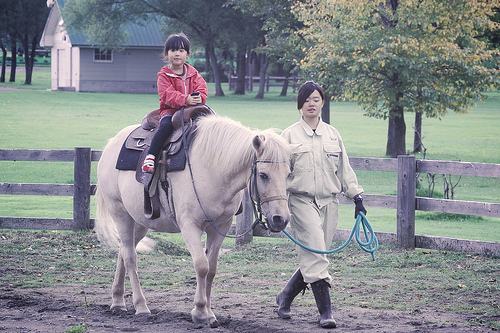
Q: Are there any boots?
A: Yes, there are boots.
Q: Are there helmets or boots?
A: Yes, there are boots.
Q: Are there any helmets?
A: No, there are no helmets.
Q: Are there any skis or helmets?
A: No, there are no helmets or skis.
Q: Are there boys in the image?
A: No, there are no boys.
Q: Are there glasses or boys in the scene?
A: No, there are no boys or glasses.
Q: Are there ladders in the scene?
A: No, there are no ladders.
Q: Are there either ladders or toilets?
A: No, there are no ladders or toilets.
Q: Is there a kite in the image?
A: No, there are no kites.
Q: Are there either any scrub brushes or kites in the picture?
A: No, there are no kites or scrub brushes.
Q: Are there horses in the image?
A: Yes, there is a horse.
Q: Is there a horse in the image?
A: Yes, there is a horse.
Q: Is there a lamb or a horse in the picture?
A: Yes, there is a horse.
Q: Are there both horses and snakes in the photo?
A: No, there is a horse but no snakes.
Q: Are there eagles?
A: No, there are no eagles.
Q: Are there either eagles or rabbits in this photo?
A: No, there are no eagles or rabbits.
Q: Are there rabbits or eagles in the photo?
A: No, there are no eagles or rabbits.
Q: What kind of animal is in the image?
A: The animal is a horse.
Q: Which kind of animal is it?
A: The animal is a horse.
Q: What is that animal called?
A: This is a horse.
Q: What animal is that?
A: This is a horse.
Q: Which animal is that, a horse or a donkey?
A: This is a horse.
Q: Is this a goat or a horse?
A: This is a horse.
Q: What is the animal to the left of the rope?
A: The animal is a horse.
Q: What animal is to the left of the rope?
A: The animal is a horse.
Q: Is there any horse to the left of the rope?
A: Yes, there is a horse to the left of the rope.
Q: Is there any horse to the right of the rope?
A: No, the horse is to the left of the rope.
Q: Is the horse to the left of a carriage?
A: No, the horse is to the left of a rope.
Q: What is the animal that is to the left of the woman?
A: The animal is a horse.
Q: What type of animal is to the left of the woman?
A: The animal is a horse.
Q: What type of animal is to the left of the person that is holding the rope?
A: The animal is a horse.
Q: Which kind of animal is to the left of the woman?
A: The animal is a horse.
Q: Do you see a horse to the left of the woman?
A: Yes, there is a horse to the left of the woman.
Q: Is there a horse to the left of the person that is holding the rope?
A: Yes, there is a horse to the left of the woman.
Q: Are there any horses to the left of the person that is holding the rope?
A: Yes, there is a horse to the left of the woman.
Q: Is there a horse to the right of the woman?
A: No, the horse is to the left of the woman.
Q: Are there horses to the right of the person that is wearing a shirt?
A: No, the horse is to the left of the woman.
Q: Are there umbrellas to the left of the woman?
A: No, there is a horse to the left of the woman.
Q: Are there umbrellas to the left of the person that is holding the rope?
A: No, there is a horse to the left of the woman.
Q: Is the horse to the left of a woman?
A: Yes, the horse is to the left of a woman.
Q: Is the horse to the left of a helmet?
A: No, the horse is to the left of a woman.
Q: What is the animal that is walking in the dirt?
A: The animal is a horse.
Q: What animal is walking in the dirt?
A: The animal is a horse.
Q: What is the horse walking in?
A: The horse is walking in the dirt.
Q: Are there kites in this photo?
A: No, there are no kites.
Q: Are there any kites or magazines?
A: No, there are no kites or magazines.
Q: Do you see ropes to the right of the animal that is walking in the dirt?
A: Yes, there is a rope to the right of the horse.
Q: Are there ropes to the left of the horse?
A: No, the rope is to the right of the horse.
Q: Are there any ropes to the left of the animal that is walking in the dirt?
A: No, the rope is to the right of the horse.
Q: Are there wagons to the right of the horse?
A: No, there is a rope to the right of the horse.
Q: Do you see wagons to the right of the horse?
A: No, there is a rope to the right of the horse.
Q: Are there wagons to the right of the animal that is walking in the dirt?
A: No, there is a rope to the right of the horse.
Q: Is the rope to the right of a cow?
A: No, the rope is to the right of the horse.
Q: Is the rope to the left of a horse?
A: No, the rope is to the right of a horse.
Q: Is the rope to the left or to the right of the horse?
A: The rope is to the right of the horse.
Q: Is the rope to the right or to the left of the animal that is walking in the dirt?
A: The rope is to the right of the horse.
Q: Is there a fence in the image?
A: Yes, there is a fence.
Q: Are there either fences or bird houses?
A: Yes, there is a fence.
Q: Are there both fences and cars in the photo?
A: No, there is a fence but no cars.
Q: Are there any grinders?
A: No, there are no grinders.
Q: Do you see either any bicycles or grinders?
A: No, there are no grinders or bicycles.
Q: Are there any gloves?
A: Yes, there are gloves.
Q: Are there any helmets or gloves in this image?
A: Yes, there are gloves.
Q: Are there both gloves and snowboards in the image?
A: No, there are gloves but no snowboards.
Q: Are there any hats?
A: No, there are no hats.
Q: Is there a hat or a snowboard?
A: No, there are no hats or snowboards.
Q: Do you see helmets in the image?
A: No, there are no helmets.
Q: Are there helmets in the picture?
A: No, there are no helmets.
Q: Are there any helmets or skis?
A: No, there are no helmets or skis.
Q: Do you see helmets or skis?
A: No, there are no helmets or skis.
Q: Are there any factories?
A: No, there are no factories.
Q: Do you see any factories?
A: No, there are no factories.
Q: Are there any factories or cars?
A: No, there are no factories or cars.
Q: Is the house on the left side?
A: Yes, the house is on the left of the image.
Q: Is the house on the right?
A: No, the house is on the left of the image.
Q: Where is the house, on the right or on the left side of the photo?
A: The house is on the left of the image.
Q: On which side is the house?
A: The house is on the left of the image.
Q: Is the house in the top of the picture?
A: Yes, the house is in the top of the image.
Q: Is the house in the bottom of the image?
A: No, the house is in the top of the image.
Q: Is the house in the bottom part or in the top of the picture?
A: The house is in the top of the image.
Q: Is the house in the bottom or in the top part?
A: The house is in the top of the image.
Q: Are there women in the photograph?
A: Yes, there is a woman.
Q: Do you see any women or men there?
A: Yes, there is a woman.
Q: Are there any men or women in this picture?
A: Yes, there is a woman.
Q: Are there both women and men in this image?
A: No, there is a woman but no men.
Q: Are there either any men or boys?
A: No, there are no boys or men.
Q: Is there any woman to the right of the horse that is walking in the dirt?
A: Yes, there is a woman to the right of the horse.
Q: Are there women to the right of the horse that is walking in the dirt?
A: Yes, there is a woman to the right of the horse.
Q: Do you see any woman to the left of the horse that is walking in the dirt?
A: No, the woman is to the right of the horse.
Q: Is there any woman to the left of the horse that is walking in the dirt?
A: No, the woman is to the right of the horse.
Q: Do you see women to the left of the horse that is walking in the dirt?
A: No, the woman is to the right of the horse.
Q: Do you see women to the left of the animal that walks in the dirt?
A: No, the woman is to the right of the horse.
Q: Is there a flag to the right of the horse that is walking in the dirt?
A: No, there is a woman to the right of the horse.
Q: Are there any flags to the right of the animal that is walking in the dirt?
A: No, there is a woman to the right of the horse.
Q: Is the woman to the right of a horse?
A: Yes, the woman is to the right of a horse.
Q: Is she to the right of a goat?
A: No, the woman is to the right of a horse.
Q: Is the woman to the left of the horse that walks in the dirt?
A: No, the woman is to the right of the horse.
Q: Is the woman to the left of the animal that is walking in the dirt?
A: No, the woman is to the right of the horse.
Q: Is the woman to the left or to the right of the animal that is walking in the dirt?
A: The woman is to the right of the horse.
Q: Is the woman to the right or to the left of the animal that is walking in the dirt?
A: The woman is to the right of the horse.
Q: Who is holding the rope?
A: The woman is holding the rope.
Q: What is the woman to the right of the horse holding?
A: The woman is holding the rope.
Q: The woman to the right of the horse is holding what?
A: The woman is holding the rope.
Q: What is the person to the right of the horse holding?
A: The woman is holding the rope.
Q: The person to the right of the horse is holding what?
A: The woman is holding the rope.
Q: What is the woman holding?
A: The woman is holding the rope.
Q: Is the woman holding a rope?
A: Yes, the woman is holding a rope.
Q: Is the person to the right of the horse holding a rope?
A: Yes, the woman is holding a rope.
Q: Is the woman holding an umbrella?
A: No, the woman is holding a rope.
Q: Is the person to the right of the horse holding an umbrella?
A: No, the woman is holding a rope.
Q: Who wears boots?
A: The woman wears boots.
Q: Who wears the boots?
A: The woman wears boots.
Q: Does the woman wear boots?
A: Yes, the woman wears boots.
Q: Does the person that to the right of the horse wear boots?
A: Yes, the woman wears boots.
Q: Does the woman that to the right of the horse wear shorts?
A: No, the woman wears boots.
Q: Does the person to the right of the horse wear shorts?
A: No, the woman wears boots.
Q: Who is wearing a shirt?
A: The woman is wearing a shirt.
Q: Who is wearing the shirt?
A: The woman is wearing a shirt.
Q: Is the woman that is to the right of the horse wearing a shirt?
A: Yes, the woman is wearing a shirt.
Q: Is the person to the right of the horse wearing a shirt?
A: Yes, the woman is wearing a shirt.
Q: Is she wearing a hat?
A: No, the woman is wearing a shirt.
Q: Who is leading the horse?
A: The woman is leading the horse.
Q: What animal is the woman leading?
A: The woman is leading the horse.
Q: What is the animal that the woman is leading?
A: The animal is a horse.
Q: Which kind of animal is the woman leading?
A: The woman is leading the horse.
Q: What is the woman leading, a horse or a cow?
A: The woman is leading a horse.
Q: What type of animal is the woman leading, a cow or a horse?
A: The woman is leading a horse.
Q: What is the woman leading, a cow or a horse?
A: The woman is leading a horse.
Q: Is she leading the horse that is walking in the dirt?
A: Yes, the woman is leading the horse.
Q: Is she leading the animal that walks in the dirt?
A: Yes, the woman is leading the horse.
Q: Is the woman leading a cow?
A: No, the woman is leading the horse.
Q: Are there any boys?
A: No, there are no boys.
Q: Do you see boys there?
A: No, there are no boys.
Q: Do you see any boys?
A: No, there are no boys.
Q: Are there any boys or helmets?
A: No, there are no boys or helmets.